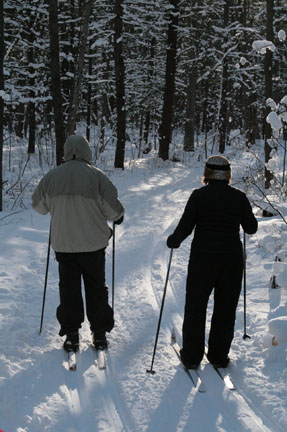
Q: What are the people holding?
A: Ski poles.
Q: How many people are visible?
A: Two.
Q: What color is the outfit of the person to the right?
A: Black.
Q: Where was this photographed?
A: Forest.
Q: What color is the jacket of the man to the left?
A: Gray.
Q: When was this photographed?
A: Daytime.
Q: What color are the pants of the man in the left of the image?
A: Black.